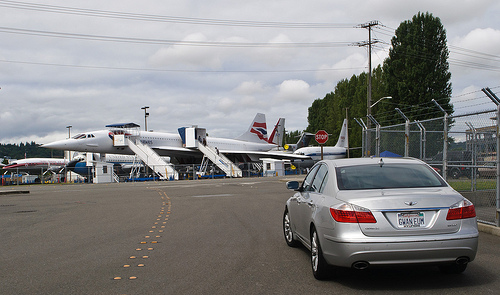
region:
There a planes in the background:
[16, 30, 471, 275]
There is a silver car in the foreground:
[269, 109, 490, 284]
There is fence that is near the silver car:
[235, 80, 495, 275]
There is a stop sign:
[295, 111, 356, 176]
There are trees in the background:
[237, 30, 487, 152]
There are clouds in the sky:
[32, 35, 412, 195]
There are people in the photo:
[16, 67, 476, 287]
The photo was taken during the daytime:
[46, 8, 417, 293]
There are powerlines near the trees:
[22, 13, 478, 128]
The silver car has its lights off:
[277, 106, 492, 287]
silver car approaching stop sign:
[281, 154, 481, 278]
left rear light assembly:
[326, 201, 378, 226]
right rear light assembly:
[445, 198, 480, 220]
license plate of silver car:
[396, 211, 427, 227]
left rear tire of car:
[309, 228, 328, 280]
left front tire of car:
[281, 206, 294, 242]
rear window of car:
[333, 159, 447, 189]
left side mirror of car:
[284, 179, 300, 190]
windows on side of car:
[297, 160, 327, 195]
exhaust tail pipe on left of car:
[353, 260, 368, 272]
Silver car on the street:
[230, 118, 492, 283]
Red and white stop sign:
[303, 122, 331, 156]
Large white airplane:
[21, 103, 311, 184]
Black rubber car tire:
[297, 221, 337, 289]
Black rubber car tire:
[269, 203, 305, 255]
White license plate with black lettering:
[392, 206, 429, 233]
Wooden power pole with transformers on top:
[349, 11, 394, 170]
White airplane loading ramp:
[173, 119, 255, 180]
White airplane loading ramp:
[109, 120, 179, 195]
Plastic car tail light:
[323, 195, 383, 235]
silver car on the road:
[271, 146, 481, 276]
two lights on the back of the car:
[327, 195, 477, 232]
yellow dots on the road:
[106, 180, 188, 294]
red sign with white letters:
[312, 128, 334, 145]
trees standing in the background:
[298, 38, 455, 158]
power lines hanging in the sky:
[6, 2, 494, 71]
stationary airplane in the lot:
[47, 112, 310, 182]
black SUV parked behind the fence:
[423, 143, 490, 183]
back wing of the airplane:
[243, 112, 274, 154]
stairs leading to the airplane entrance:
[108, 129, 181, 192]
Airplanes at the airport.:
[0, 112, 354, 180]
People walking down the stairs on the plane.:
[186, 130, 240, 177]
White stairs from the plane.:
[127, 136, 179, 180]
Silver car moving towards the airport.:
[286, 156, 479, 283]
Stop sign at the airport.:
[302, 131, 333, 195]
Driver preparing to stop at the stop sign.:
[271, 128, 481, 281]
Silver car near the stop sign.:
[282, 127, 481, 282]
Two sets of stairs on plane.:
[110, 122, 244, 179]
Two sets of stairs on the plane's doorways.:
[112, 127, 242, 178]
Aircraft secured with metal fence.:
[1, 112, 318, 184]